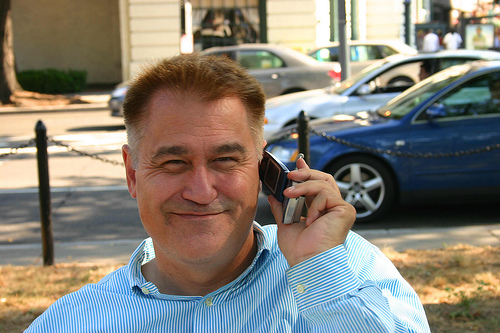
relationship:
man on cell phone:
[115, 40, 385, 307] [258, 135, 321, 231]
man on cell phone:
[22, 50, 434, 333] [256, 150, 303, 225]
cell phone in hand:
[260, 148, 305, 225] [267, 153, 357, 258]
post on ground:
[32, 118, 55, 265] [0, 107, 498, 331]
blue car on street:
[280, 57, 497, 222] [1, 110, 498, 255]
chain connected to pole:
[3, 121, 127, 179] [30, 117, 58, 266]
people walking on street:
[416, 22, 466, 53] [0, 68, 497, 264]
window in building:
[194, 0, 280, 49] [12, 3, 432, 93]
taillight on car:
[326, 65, 342, 81] [111, 40, 341, 113]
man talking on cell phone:
[22, 50, 434, 333] [259, 153, 306, 223]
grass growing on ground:
[2, 243, 498, 331] [0, 107, 498, 331]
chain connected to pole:
[47, 137, 126, 182] [32, 117, 61, 265]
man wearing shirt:
[22, 50, 434, 333] [14, 218, 429, 331]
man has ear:
[22, 50, 434, 333] [121, 143, 136, 196]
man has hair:
[22, 50, 434, 333] [129, 116, 145, 167]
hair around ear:
[129, 116, 145, 167] [121, 143, 136, 196]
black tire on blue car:
[321, 151, 396, 222] [264, 59, 500, 225]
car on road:
[100, 43, 342, 120] [3, 108, 499, 252]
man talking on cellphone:
[22, 50, 434, 333] [260, 149, 307, 224]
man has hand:
[22, 50, 434, 333] [267, 153, 357, 258]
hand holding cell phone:
[267, 153, 357, 258] [257, 149, 305, 226]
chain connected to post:
[0, 139, 35, 161] [29, 118, 58, 265]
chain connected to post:
[0, 139, 35, 161] [295, 109, 308, 168]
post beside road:
[29, 118, 58, 265] [6, 182, 497, 263]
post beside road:
[295, 109, 308, 168] [6, 182, 497, 263]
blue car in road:
[264, 59, 500, 225] [6, 182, 497, 263]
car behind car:
[281, 41, 461, 112] [321, 67, 472, 149]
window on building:
[194, 0, 280, 49] [9, 0, 429, 85]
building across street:
[9, 0, 429, 85] [4, 105, 263, 245]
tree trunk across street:
[2, 1, 27, 106] [2, 104, 152, 264]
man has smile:
[22, 50, 434, 333] [163, 206, 235, 223]